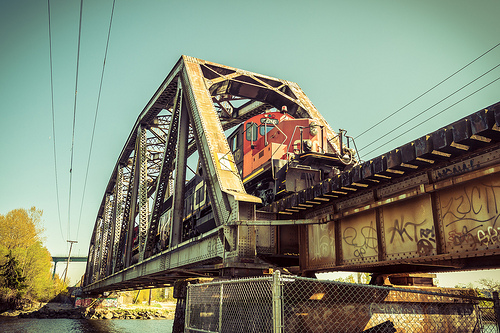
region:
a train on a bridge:
[105, 108, 352, 216]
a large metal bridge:
[84, 53, 349, 285]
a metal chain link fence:
[186, 272, 496, 332]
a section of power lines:
[45, 0, 117, 294]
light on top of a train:
[281, 103, 286, 111]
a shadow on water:
[73, 315, 123, 331]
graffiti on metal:
[382, 205, 434, 255]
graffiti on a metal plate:
[340, 220, 377, 261]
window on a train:
[245, 121, 256, 142]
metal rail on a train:
[293, 120, 350, 155]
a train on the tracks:
[70, 99, 372, 292]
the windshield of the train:
[243, 120, 281, 145]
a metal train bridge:
[74, 53, 369, 310]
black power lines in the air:
[44, 0, 118, 253]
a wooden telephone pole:
[56, 234, 78, 287]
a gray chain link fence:
[178, 268, 498, 332]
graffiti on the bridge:
[300, 170, 497, 270]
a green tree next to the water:
[0, 198, 75, 298]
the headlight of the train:
[303, 117, 323, 140]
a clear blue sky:
[1, 0, 499, 291]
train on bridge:
[222, 94, 379, 209]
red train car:
[237, 110, 354, 175]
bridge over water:
[64, 56, 495, 328]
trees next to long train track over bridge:
[4, 204, 69, 320]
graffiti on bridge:
[325, 192, 491, 252]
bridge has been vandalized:
[277, 187, 495, 262]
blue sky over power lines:
[14, 13, 489, 192]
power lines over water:
[43, 4, 112, 261]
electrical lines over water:
[40, 1, 110, 258]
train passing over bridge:
[79, 100, 356, 286]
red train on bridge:
[234, 99, 348, 173]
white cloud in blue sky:
[11, 10, 107, 78]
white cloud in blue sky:
[18, 50, 118, 119]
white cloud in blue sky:
[3, 91, 98, 140]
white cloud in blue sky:
[34, 135, 84, 171]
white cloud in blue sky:
[35, 148, 79, 232]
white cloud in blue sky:
[100, 10, 263, 44]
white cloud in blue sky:
[273, 18, 358, 40]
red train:
[243, 94, 335, 171]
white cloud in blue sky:
[318, 13, 365, 70]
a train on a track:
[86, 61, 493, 277]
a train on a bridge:
[107, 54, 464, 329]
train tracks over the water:
[100, 45, 492, 315]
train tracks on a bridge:
[62, 93, 457, 325]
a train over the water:
[62, 22, 490, 259]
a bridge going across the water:
[30, 96, 424, 331]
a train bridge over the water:
[43, 58, 453, 325]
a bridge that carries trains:
[72, 52, 472, 300]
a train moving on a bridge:
[105, 83, 493, 323]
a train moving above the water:
[71, 37, 403, 249]